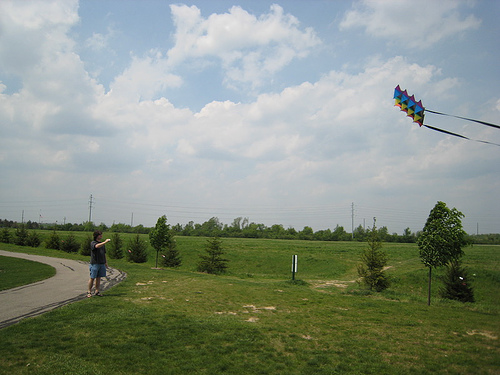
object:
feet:
[86, 292, 105, 299]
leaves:
[431, 224, 452, 246]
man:
[86, 230, 111, 298]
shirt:
[89, 240, 106, 264]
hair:
[93, 231, 103, 241]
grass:
[257, 326, 408, 375]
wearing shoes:
[84, 275, 106, 298]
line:
[0, 225, 500, 248]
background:
[1, 0, 500, 269]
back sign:
[291, 254, 299, 280]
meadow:
[0, 267, 500, 375]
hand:
[106, 239, 112, 243]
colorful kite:
[391, 84, 500, 147]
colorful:
[409, 102, 421, 115]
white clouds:
[157, 97, 243, 136]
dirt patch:
[213, 293, 279, 323]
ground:
[0, 263, 119, 322]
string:
[422, 109, 499, 146]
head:
[93, 231, 102, 240]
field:
[0, 250, 497, 375]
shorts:
[89, 264, 107, 279]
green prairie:
[32, 229, 499, 374]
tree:
[416, 200, 470, 306]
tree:
[357, 216, 392, 292]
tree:
[194, 235, 232, 276]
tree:
[148, 214, 173, 269]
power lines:
[0, 194, 500, 241]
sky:
[0, 0, 499, 234]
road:
[0, 249, 129, 332]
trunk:
[422, 255, 438, 313]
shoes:
[86, 292, 104, 298]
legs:
[87, 265, 101, 291]